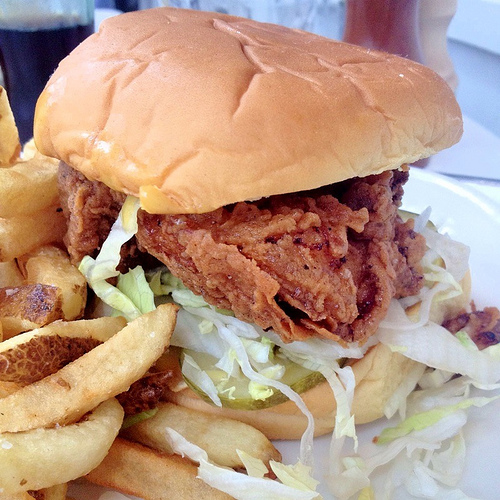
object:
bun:
[31, 8, 461, 222]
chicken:
[52, 173, 427, 302]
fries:
[0, 305, 176, 432]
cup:
[0, 1, 99, 153]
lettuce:
[72, 199, 267, 402]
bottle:
[338, 5, 420, 70]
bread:
[164, 210, 474, 440]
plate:
[258, 165, 498, 497]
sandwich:
[26, 5, 473, 444]